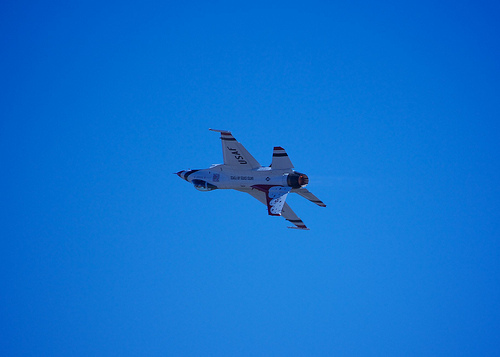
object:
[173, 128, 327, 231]
jet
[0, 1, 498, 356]
sky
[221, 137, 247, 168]
logo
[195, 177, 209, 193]
pilot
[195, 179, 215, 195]
cockpit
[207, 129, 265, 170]
wing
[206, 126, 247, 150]
stripes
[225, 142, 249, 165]
letters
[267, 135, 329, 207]
tail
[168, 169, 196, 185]
nose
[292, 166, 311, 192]
afterburner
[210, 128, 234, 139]
tip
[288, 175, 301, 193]
engine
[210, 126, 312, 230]
wingspan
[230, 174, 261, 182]
writing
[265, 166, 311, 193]
rear